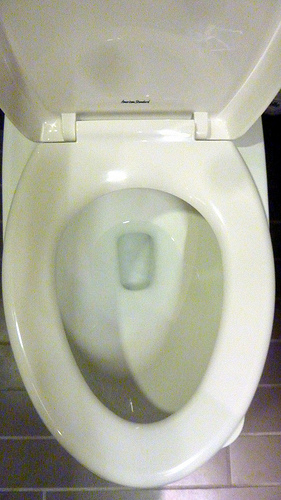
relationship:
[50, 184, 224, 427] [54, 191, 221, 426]
water in toilet bowl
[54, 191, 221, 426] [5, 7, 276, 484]
toilet bowl in toilet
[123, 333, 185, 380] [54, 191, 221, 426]
water in toilet bowl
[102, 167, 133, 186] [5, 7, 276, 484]
light glare on toilet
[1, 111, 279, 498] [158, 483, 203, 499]
floor has a glare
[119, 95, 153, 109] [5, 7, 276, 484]
brand of toilet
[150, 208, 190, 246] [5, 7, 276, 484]
reflection in toilet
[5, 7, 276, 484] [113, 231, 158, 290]
toilet has a drain hole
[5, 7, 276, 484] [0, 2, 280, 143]
toilet has a seat lid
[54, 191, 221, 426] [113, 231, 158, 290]
toilet bowl has a water drain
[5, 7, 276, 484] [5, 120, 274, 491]
toilet has a seat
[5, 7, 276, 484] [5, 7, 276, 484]
bathroom has a toilet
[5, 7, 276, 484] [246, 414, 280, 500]
bathroom has tiled floor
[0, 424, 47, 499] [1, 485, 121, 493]
tile with white grout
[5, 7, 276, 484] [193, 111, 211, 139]
toilet has a seat hinge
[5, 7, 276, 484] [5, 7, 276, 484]
bathroom has a clean toilet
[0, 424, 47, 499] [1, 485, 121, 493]
tile has white grout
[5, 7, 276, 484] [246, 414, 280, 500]
bathroom has brown tile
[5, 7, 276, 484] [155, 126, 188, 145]
toilet has a light glare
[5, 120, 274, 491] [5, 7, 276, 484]
toilet seat on toilet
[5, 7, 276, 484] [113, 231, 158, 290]
toilet has a water drain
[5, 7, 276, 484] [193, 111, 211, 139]
toilet has a seat lid hinge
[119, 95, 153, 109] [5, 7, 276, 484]
brand name on toilet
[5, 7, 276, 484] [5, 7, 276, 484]
bathroom has a white toilet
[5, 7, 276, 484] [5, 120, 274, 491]
toilet has a beige seat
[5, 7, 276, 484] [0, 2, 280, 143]
toilet has a seat cover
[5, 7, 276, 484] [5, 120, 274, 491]
toilet has a used toilet seat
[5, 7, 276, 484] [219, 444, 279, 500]
bathroom has rectangle tiles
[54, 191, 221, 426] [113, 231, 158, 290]
toilet bowl has a round drain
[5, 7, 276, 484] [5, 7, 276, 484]
bathroom has a used toilet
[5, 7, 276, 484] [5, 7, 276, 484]
toilet in a bathroom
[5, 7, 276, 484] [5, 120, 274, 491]
toilet has a worn seat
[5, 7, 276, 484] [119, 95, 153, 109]
toilet has brand logo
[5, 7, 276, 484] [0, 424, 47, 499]
bathroom has dark tiles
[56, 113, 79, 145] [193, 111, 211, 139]
toilet has a seat hinge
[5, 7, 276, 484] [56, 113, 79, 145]
toilet has a toilet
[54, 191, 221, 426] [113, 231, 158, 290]
toilet bowl has a drain hole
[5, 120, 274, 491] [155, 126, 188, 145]
seat has a light glare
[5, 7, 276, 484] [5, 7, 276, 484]
toilet in bathroom